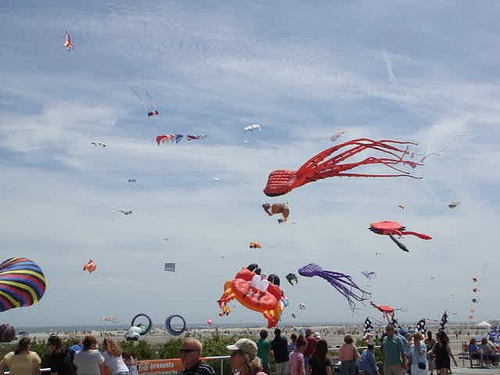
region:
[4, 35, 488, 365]
the phto was taken during the dsay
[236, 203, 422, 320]
kites being flown people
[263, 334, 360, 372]
people flying their kites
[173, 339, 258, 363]
people walking along the kite fest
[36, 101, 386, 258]
the weather looks windy and sunny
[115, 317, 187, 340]
kite rings on the air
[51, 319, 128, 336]
hills can be seen from a far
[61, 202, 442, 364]
all this kites look beautiful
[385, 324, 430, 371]
a man and his wife walking along the road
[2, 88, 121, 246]
the sky looks beautiful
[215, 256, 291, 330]
a large crab shaped kite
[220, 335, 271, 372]
a woman in a baseball cap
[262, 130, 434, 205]
a red kite with many tails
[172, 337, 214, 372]
a man wearing sunglasses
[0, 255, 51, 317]
a kite with multicolored stripes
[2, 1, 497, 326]
a sky full of kites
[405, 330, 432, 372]
a woman carrying a black purse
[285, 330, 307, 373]
a young woman in a pink shirt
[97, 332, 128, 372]
the back of a woman with long hair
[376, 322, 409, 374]
a man in a light green short sleeved shirt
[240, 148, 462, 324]
kites are in the air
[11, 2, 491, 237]
the sky is clear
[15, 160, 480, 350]
the photo was taken outdoors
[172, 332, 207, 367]
the man is wearing glasses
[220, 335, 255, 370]
the lady is wearing a hat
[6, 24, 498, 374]
the photo was taken during the day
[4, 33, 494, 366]
the photo is clear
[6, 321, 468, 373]
people are in the photo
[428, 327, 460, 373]
the ladies dress is black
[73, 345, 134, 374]
this people are wearing white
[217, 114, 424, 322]
Flying colored objects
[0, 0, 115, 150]
A sunny Sky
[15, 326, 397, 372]
A group of different kind of people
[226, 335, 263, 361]
A Woman with a white Lid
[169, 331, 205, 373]
A man with a Sunny eyeglass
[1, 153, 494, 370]
A kite tournament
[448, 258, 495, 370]
Different Colors flying balloons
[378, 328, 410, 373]
A man in a blue shirt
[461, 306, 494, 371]
A couple of friends talking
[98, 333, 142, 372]
A woman with a blonde hair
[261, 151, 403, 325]
Flying kites.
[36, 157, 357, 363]
Kites on the beach.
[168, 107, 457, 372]
Gathering to watch the kites fly.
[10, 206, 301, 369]
Nice day on the beach.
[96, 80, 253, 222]
Kites in the sky.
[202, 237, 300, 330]
Crab kite flying in the air.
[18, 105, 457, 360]
Strong winds for flying kites.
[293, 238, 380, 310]
Purple jellyfish kite.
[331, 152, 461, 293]
Kite in the wind.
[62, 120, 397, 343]
Nice day on the beach.